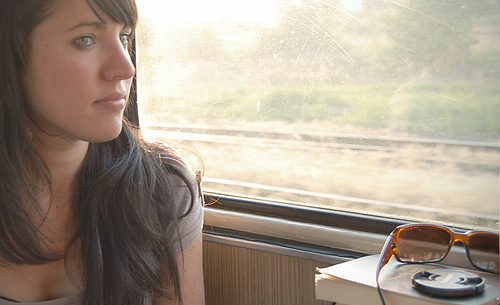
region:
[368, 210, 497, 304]
sun glasses sitting on top of book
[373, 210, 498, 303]
big brown sun glasses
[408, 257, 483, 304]
black object on top of book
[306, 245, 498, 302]
book under sun glasses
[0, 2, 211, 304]
woman staring in the distance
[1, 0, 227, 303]
the person is a woman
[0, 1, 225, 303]
the woman is a brunette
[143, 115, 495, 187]
tracks outside of the window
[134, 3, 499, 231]
scratchy and blurry window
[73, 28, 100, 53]
blue eye of the woman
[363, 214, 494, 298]
sunglasses on a book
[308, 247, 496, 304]
book on a shelf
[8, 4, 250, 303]
woman sitting on a train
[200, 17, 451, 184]
window of a train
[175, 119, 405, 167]
tracks for a train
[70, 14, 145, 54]
eyes of a woman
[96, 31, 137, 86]
nose on a woman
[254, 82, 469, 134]
green bushes outside window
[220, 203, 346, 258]
bottom of a train window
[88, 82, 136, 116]
lips on a woman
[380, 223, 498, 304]
Sunglasses on a book.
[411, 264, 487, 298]
Round object on a book.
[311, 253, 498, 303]
An unopened book near a window.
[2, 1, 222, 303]
A female near a window.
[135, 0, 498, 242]
Large window of a train.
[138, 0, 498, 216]
Scenery outside a train window.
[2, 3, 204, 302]
Woman with long hair.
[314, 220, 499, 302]
Sunglasses and a book next to each other.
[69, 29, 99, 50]
The eye of a woman.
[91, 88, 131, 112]
Lips of a woman.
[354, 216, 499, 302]
the sunglasses is on the book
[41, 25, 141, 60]
the eyes are open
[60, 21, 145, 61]
the eyes are bluish green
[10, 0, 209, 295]
the girl has long hair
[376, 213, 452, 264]
the glasses are reflecting objects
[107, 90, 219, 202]
the sun is on the girl`s shoulder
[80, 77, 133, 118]
the mouth is closed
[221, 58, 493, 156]
bushes are on the side of the tracks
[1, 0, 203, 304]
The woman is wearing a light brown shirt.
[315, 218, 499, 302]
A pair of glasses is on top of the book.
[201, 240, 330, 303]
The wall has a finish to make it look like wood.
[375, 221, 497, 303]
Light is shining on the sunglasses.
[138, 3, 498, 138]
Trees and bushes are outside of the window.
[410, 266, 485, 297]
A small black lid.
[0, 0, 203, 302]
The woman has long brown hair.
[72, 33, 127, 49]
The woman's eyes are green.